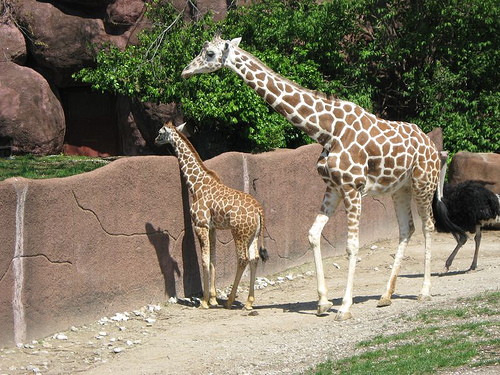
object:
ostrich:
[438, 147, 500, 274]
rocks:
[0, 15, 32, 64]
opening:
[59, 83, 119, 157]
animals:
[153, 29, 499, 320]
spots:
[336, 141, 366, 160]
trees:
[368, 0, 485, 155]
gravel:
[9, 340, 55, 367]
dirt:
[6, 236, 498, 371]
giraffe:
[183, 31, 444, 319]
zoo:
[0, 0, 499, 374]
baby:
[153, 119, 268, 314]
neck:
[440, 163, 447, 201]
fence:
[3, 130, 499, 344]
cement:
[0, 126, 498, 345]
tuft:
[439, 202, 464, 246]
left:
[6, 6, 230, 367]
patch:
[0, 154, 100, 179]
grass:
[1, 154, 98, 177]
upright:
[438, 148, 500, 278]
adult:
[436, 151, 499, 280]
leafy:
[73, 5, 496, 147]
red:
[62, 87, 116, 156]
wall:
[3, 5, 222, 152]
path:
[7, 237, 500, 374]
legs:
[334, 187, 362, 320]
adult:
[178, 34, 442, 318]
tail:
[257, 210, 274, 261]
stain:
[13, 179, 38, 343]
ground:
[7, 236, 490, 375]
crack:
[0, 180, 385, 279]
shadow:
[141, 167, 206, 297]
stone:
[444, 149, 500, 228]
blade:
[327, 296, 496, 374]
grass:
[303, 293, 491, 375]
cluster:
[328, 299, 497, 374]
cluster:
[80, 2, 499, 147]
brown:
[226, 200, 240, 210]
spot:
[345, 208, 355, 220]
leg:
[337, 193, 361, 319]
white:
[347, 254, 353, 310]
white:
[108, 312, 125, 321]